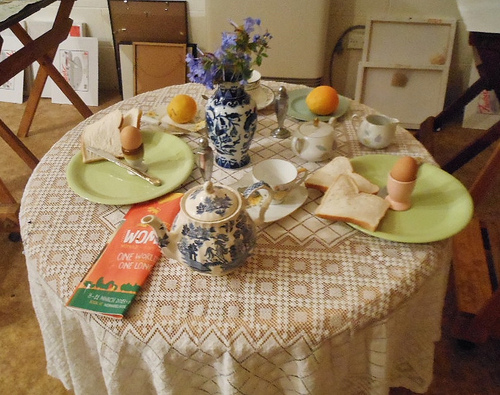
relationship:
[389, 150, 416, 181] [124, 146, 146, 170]
eggs in egg holders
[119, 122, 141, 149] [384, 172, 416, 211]
eggs in cup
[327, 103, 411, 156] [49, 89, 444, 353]
creamer on table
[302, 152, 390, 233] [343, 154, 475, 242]
bread on a green plate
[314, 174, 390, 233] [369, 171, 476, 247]
bread on green plate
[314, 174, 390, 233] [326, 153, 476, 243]
bread on a plate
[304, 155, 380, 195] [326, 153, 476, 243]
bread on a plate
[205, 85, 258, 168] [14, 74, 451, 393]
shakers on table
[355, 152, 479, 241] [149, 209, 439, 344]
green plate on table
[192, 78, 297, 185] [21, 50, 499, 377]
shakers on table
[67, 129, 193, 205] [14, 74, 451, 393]
green plate on table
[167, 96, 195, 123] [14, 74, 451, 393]
orange on table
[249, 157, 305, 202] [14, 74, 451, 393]
cup on a table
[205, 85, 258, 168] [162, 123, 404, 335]
shakers on a table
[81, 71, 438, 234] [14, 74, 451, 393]
food on table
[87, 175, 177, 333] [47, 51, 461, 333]
paper on table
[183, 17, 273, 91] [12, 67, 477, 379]
flowers on table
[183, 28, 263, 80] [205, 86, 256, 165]
flowers in vase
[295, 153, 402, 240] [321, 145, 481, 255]
bread on plate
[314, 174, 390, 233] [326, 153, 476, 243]
bread on plate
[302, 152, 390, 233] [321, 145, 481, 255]
bread on plate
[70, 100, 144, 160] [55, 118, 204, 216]
bread on plate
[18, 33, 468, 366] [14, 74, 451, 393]
table cloth on table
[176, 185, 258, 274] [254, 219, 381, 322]
tea kettle on table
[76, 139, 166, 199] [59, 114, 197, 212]
knife on plate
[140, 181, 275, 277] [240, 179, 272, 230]
tea kettle has handle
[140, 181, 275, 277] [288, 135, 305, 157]
tea kettle has handle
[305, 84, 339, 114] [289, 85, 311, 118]
grapefruit on plate